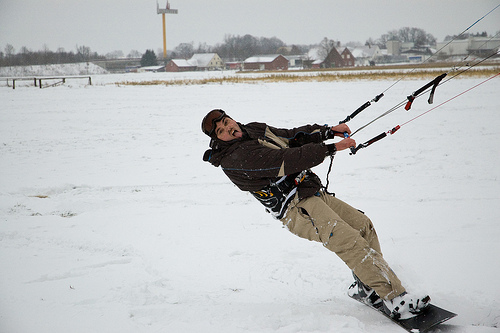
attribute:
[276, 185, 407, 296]
pants — tan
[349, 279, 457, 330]
board — black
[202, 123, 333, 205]
coat — brown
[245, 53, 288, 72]
building — red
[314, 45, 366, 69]
building — tan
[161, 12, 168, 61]
pole — yellow